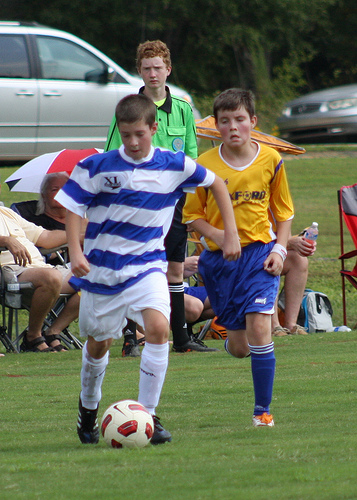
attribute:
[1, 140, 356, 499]
grass — short, green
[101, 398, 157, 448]
ball — white, red, a soccerball, round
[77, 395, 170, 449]
shoes — black, white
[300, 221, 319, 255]
bottle — plastic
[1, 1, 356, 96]
trees — leafy, green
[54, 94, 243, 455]
boy — playing, playing soccer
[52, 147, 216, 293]
shirt — white, blue, striped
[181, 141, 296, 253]
jersey — yellow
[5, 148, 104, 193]
umbrella — open, white, red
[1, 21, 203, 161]
van — parked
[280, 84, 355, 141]
car — silver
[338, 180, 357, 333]
chair — red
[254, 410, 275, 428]
shoe — orange, white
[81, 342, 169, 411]
shin guards — white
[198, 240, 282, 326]
shorts — blue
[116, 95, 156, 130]
hair — short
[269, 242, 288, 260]
wristband — white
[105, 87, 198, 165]
shirt — green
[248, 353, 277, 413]
shin guards — blue